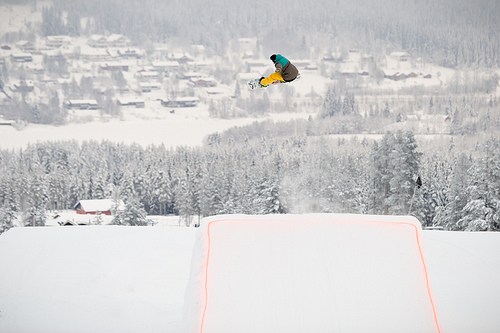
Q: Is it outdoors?
A: Yes, it is outdoors.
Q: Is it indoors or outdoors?
A: It is outdoors.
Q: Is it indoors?
A: No, it is outdoors.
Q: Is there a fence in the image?
A: No, there are no fences.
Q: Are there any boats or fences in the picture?
A: No, there are no fences or boats.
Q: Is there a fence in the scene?
A: No, there are no fences.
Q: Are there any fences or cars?
A: No, there are no fences or cars.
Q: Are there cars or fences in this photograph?
A: No, there are no fences or cars.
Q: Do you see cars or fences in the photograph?
A: No, there are no fences or cars.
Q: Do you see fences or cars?
A: No, there are no fences or cars.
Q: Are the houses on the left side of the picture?
A: Yes, the houses are on the left of the image.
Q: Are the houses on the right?
A: No, the houses are on the left of the image.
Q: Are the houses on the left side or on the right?
A: The houses are on the left of the image.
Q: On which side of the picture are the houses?
A: The houses are on the left of the image.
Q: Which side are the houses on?
A: The houses are on the left of the image.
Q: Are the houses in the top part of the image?
A: Yes, the houses are in the top of the image.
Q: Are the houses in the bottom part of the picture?
A: No, the houses are in the top of the image.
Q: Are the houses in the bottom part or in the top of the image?
A: The houses are in the top of the image.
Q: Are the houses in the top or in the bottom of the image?
A: The houses are in the top of the image.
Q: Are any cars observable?
A: No, there are no cars.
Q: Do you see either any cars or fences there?
A: No, there are no cars or fences.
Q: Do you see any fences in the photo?
A: No, there are no fences.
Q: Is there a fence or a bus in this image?
A: No, there are no buses or fences.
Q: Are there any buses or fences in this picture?
A: No, there are no buses or fences.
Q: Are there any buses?
A: No, there are no buses.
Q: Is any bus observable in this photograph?
A: No, there are no buses.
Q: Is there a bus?
A: No, there are no buses.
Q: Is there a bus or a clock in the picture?
A: No, there are no buses or clocks.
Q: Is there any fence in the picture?
A: No, there are no fences.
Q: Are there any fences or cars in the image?
A: No, there are no fences or cars.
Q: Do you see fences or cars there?
A: No, there are no fences or cars.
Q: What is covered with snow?
A: The trees are covered with snow.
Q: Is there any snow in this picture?
A: Yes, there is snow.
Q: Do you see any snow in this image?
A: Yes, there is snow.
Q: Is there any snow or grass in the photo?
A: Yes, there is snow.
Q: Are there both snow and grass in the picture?
A: No, there is snow but no grass.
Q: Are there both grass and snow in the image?
A: No, there is snow but no grass.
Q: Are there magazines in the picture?
A: No, there are no magazines.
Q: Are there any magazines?
A: No, there are no magazines.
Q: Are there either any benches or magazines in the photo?
A: No, there are no magazines or benches.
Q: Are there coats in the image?
A: Yes, there is a coat.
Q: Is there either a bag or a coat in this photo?
A: Yes, there is a coat.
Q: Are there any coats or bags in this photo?
A: Yes, there is a coat.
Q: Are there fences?
A: No, there are no fences.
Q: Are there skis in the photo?
A: No, there are no skis.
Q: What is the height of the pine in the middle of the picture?
A: The pine is tall.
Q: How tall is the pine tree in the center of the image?
A: The pine is tall.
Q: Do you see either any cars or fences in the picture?
A: No, there are no cars or fences.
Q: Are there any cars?
A: No, there are no cars.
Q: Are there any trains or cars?
A: No, there are no cars or trains.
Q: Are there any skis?
A: No, there are no skis.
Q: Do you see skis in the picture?
A: No, there are no skis.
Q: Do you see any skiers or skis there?
A: No, there are no skis or skiers.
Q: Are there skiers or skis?
A: No, there are no skis or skiers.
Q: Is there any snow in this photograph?
A: Yes, there is snow.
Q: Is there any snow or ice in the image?
A: Yes, there is snow.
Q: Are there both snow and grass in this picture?
A: No, there is snow but no grass.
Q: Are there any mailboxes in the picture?
A: No, there are no mailboxes.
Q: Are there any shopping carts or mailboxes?
A: No, there are no mailboxes or shopping carts.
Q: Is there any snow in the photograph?
A: Yes, there is snow.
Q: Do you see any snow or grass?
A: Yes, there is snow.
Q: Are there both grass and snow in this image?
A: No, there is snow but no grass.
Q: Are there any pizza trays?
A: No, there are no pizza trays.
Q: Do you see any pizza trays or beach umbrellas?
A: No, there are no pizza trays or beach umbrellas.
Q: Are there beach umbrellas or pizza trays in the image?
A: No, there are no pizza trays or beach umbrellas.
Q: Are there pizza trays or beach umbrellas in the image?
A: No, there are no pizza trays or beach umbrellas.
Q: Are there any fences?
A: No, there are no fences.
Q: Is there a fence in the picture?
A: No, there are no fences.